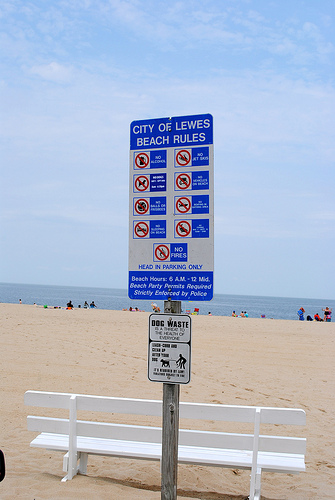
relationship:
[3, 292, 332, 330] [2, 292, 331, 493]
people on beach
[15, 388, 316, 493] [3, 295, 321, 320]
bench on beach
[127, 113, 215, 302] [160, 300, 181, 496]
post on post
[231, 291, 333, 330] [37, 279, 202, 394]
people sitting on beach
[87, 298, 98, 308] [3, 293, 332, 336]
people sitting on beach